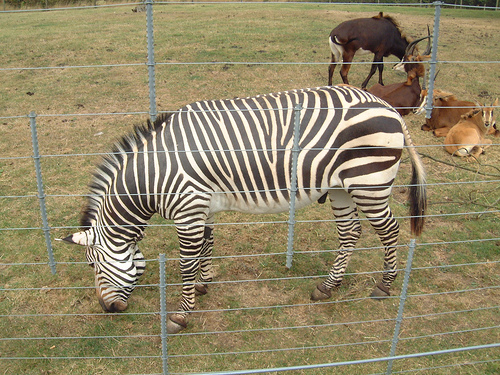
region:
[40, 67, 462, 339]
this is a zebra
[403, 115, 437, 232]
tail of the zebra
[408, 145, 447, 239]
hair on the zebra tail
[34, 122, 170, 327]
zebra has head bent down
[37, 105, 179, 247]
black and white mane on zebra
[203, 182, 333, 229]
white under belly of zebra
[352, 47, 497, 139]
animals laying on the grass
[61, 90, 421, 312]
a zebra eating the grass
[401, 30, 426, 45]
horns on the animal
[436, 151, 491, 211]
sticks on the ground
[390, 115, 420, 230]
the tail on the zebra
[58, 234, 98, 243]
the ear on the zebra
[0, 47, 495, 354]
a fence in front of the zebra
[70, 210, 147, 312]
the head of the zebra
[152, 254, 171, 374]
metal on the fence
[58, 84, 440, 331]
striped zebra eating grass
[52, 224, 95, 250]
ear of a striped zebra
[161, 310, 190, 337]
hoof of a striped zebra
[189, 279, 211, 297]
hoof of a striped zebra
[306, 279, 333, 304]
hoof of a striped zebra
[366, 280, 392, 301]
hoof of a striped zebra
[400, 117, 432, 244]
tail of a striped zebra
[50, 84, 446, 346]
zebra standing behind a fence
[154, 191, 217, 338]
leg of a striped zebra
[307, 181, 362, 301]
leg of a striped zebra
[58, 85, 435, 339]
a black and white zebra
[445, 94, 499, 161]
a hildebeast laying on the ground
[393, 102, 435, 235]
a black and white zebra tail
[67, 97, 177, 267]
a black and white zebra mane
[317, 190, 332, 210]
a black zebra penis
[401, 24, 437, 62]
black animal horns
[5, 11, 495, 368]
a silver metal wire fence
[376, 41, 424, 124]
a mouth eating grass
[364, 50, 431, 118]
a brown laying hilde beast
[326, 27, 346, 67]
a white hildebeast butt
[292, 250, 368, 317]
back right hoof on back right leg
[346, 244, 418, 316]
back left hoof on back left leg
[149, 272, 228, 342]
front left hoof attached to the front left leg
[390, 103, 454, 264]
white and black zebra tail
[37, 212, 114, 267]
beautiful black and white zebra ear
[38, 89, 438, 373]
big zebra eating green grass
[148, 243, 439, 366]
silver stainless steel fenceing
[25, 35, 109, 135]
patches of green and dead grass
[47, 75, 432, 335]
A black and white zebra is grazing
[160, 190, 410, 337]
Four legs of a zebra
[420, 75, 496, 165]
Two brown animals sitting on the grass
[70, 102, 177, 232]
The mane of a zebra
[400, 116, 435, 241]
The tail of the zebra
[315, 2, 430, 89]
A brown animal has four legs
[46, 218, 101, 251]
Pointy ear of a zebra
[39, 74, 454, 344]
A black and white striped Zebra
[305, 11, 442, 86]
Brown horned animal with head down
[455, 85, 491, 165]
young tan animal looking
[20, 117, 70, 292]
bar on the fence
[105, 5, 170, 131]
bar on the fence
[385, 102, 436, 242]
tail of the zebra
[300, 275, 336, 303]
hoof of the zebra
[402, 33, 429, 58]
horn of the animal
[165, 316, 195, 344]
hoof of the zebra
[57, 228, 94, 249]
ear of the zebra